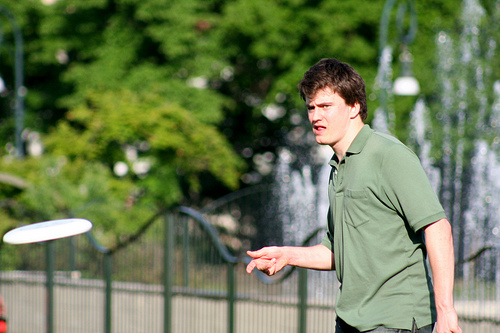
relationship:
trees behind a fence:
[2, 4, 499, 275] [5, 182, 486, 332]